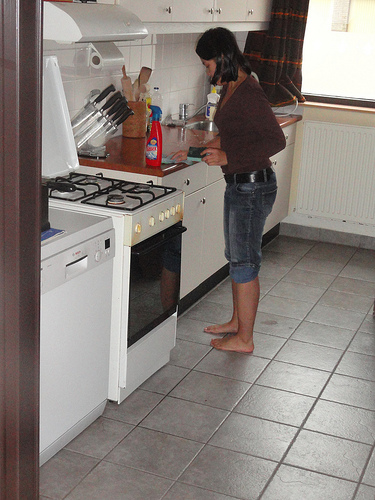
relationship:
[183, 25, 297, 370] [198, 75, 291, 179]
girl wears shirt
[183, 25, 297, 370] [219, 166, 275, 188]
girl wears belt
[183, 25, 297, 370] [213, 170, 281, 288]
girl wears jeans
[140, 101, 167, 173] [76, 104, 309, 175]
cleaner on counter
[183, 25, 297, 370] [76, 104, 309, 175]
girl cleaning counter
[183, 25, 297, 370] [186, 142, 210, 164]
girl has sponge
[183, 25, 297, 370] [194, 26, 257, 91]
girl has hair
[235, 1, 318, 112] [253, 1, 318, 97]
curtain has curtain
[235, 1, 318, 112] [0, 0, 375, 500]
curtain in kitchen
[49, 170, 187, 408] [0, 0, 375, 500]
oven in kitchen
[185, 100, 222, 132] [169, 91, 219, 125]
sink has faucet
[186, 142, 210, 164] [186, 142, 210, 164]
sponge has sponge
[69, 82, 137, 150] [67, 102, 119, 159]
knives in holder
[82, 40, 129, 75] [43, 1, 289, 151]
paper towel holder on wall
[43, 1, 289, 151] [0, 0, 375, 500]
wall in kitchen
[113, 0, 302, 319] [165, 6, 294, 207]
cabinets have knobs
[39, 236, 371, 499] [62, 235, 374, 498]
tiles have grey grout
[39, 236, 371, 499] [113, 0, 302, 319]
floor meets cabinets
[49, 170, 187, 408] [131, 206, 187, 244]
oven has stains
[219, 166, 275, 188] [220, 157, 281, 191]
belt around hips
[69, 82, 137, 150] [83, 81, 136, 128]
knives have handles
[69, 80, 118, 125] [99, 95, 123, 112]
knife has handle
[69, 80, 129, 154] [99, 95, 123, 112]
knife has handle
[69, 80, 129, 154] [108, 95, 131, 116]
knife has handle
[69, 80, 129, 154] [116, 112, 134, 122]
knife has handle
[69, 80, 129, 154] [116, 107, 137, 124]
knife has handle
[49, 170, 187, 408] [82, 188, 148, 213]
oven has burner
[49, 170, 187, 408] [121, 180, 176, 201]
oven has burner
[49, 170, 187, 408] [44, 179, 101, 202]
oven has burner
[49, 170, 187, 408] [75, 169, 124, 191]
oven has burner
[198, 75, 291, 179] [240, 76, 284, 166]
shirt has sleeves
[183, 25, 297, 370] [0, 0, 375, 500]
girl cleans kitchen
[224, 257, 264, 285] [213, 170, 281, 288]
cuffs on jeans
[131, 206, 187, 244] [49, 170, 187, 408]
stains on oven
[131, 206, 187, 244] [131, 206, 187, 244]
stains only near stains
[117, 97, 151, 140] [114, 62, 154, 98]
canister for cooking utensils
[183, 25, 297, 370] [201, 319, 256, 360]
girl has feet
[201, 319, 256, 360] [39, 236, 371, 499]
feet on floor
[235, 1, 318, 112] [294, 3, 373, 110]
curtain pulled to side of window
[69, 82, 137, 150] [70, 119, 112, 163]
knives in knife block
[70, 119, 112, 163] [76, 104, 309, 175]
knife block on counter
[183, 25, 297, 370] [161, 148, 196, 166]
girl cleans w rag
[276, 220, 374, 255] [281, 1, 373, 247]
tiles cover bottom wall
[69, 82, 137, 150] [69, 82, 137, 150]
knives have knives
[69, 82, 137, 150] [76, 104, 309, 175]
knives on counter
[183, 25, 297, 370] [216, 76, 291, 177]
girl wears sweater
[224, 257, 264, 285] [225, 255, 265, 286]
cuffs at knees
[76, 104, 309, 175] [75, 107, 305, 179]
counter has countertop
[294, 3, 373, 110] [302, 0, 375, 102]
window faces another wall